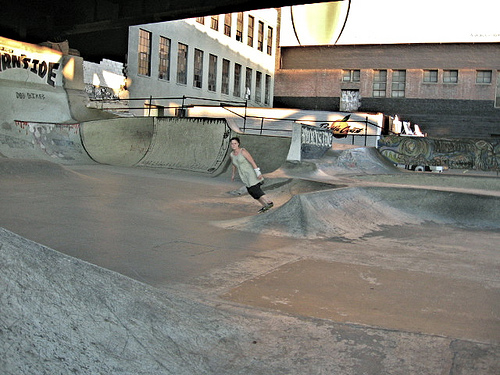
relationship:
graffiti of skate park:
[375, 132, 497, 170] [1, 34, 498, 372]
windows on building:
[334, 54, 490, 105] [287, 34, 452, 122]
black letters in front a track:
[0, 53, 60, 87] [0, 35, 499, 373]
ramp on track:
[78, 100, 304, 177] [0, 35, 499, 373]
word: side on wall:
[21, 54, 61, 90] [10, 50, 115, 112]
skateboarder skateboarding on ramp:
[229, 137, 274, 214] [220, 182, 417, 239]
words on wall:
[13, 53, 56, 82] [12, 46, 136, 193]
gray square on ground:
[156, 237, 219, 260] [0, 157, 499, 346]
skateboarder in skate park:
[220, 132, 277, 216] [1, 34, 498, 372]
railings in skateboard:
[85, 93, 394, 151] [256, 200, 274, 212]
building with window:
[125, 0, 499, 143] [138, 28, 151, 76]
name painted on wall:
[4, 54, 59, 91] [8, 24, 94, 179]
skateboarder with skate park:
[229, 137, 274, 214] [1, 34, 498, 372]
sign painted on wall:
[14, 90, 52, 102] [0, 37, 82, 128]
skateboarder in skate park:
[220, 132, 277, 216] [10, 51, 457, 373]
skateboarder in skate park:
[229, 137, 274, 214] [32, 42, 435, 240]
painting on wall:
[1, 22, 92, 132] [8, 50, 90, 177]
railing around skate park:
[91, 94, 250, 121] [0, 121, 494, 368]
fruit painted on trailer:
[329, 112, 361, 139] [222, 103, 375, 140]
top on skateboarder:
[229, 151, 262, 181] [229, 137, 274, 214]